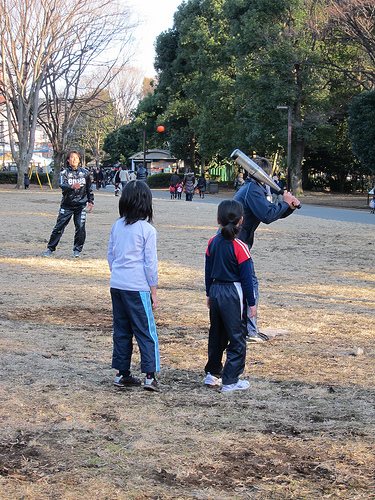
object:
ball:
[157, 125, 165, 133]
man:
[46, 150, 97, 257]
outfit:
[44, 147, 99, 260]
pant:
[110, 286, 160, 376]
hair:
[217, 199, 245, 240]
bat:
[231, 148, 303, 210]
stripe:
[140, 294, 157, 371]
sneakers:
[144, 376, 162, 393]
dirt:
[0, 184, 375, 500]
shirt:
[203, 233, 257, 307]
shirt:
[106, 216, 159, 292]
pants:
[202, 276, 248, 383]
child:
[108, 176, 163, 393]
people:
[230, 152, 302, 253]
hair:
[118, 178, 154, 227]